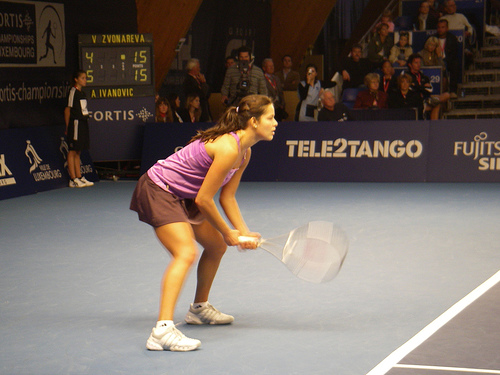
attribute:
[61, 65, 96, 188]
ballboy — waiting, patient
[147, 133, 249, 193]
shirt — purple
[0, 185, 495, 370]
tennis court — blue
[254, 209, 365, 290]
racket — blurry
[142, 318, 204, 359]
shoe — white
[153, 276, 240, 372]
sneakers — white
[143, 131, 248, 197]
top — purple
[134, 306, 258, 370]
shoe — white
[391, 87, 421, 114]
shirt — black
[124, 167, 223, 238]
tennis skirt — short, purple